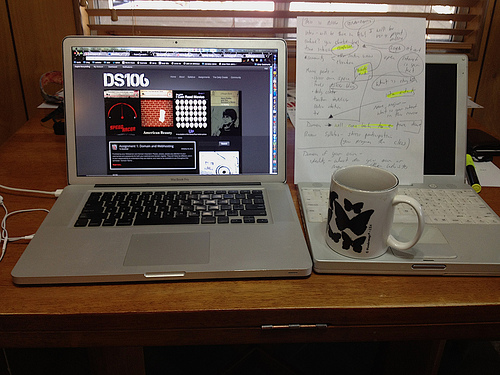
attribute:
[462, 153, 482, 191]
pen — black, yellow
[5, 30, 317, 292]
laptop — silver, gray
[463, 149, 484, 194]
marker — yellow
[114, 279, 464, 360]
surface — wooden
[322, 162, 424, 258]
b&w cup — white, black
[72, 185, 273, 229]
keys — black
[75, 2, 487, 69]
blinds — brown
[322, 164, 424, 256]
cup — black, white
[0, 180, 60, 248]
cables — white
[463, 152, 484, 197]
marker — green, black